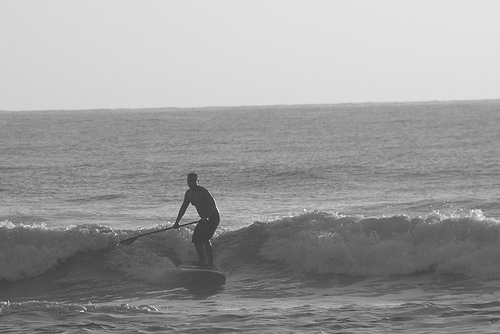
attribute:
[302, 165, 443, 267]
water — blue, gray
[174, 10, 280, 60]
sky — gray